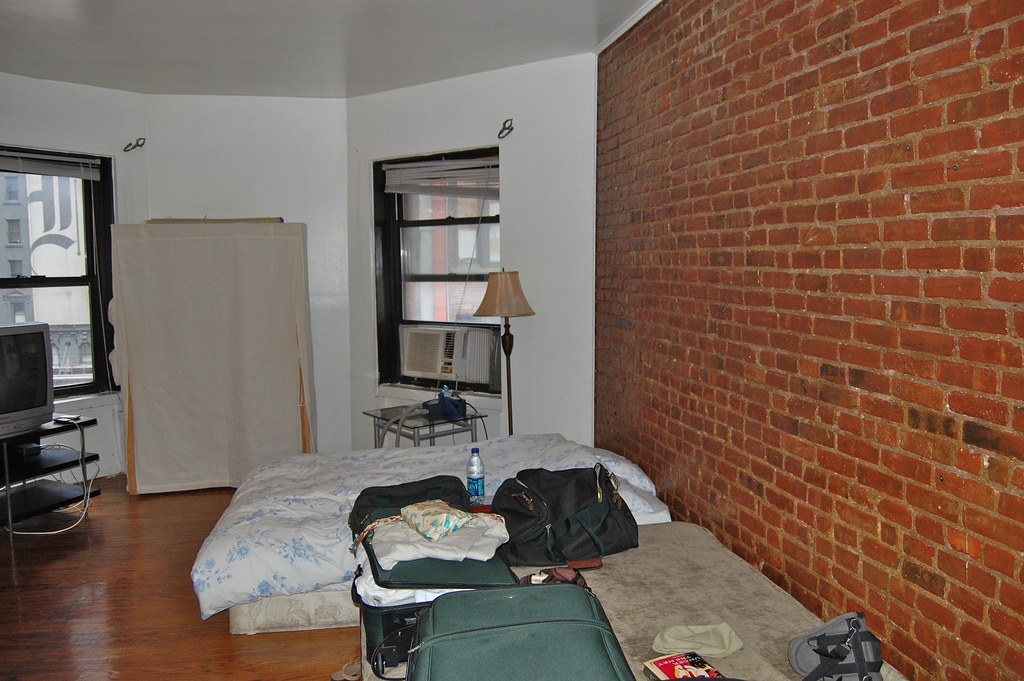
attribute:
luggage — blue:
[415, 587, 668, 671]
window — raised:
[372, 150, 513, 403]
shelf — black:
[3, 444, 96, 487]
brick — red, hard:
[884, 210, 920, 245]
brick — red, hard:
[936, 210, 993, 245]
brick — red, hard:
[901, 242, 966, 266]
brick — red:
[920, 271, 985, 306]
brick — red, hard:
[879, 298, 944, 334]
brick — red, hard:
[942, 299, 1010, 337]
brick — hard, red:
[894, 324, 962, 360]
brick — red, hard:
[879, 350, 933, 385]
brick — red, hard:
[894, 369, 940, 412]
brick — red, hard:
[857, 393, 906, 423]